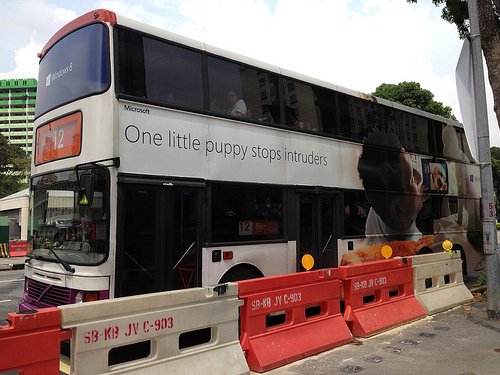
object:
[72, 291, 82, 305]
headlights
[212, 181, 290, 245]
window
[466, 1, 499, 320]
pole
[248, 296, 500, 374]
sidewalk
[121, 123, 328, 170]
writing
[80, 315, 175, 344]
lettering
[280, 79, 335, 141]
window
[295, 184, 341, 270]
door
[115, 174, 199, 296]
door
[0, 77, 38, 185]
building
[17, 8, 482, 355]
bus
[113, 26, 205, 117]
window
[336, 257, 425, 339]
barriers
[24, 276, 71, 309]
grill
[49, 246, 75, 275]
windshield wiper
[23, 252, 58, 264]
windshield wiper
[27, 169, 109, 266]
windshield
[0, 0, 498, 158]
clouds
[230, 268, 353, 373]
barricade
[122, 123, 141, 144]
black lettering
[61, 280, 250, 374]
barricade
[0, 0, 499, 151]
sky.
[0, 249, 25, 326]
street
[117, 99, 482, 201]
advert